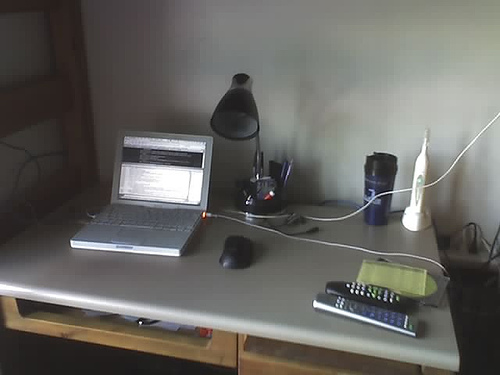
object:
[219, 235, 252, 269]
mouse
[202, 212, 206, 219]
indicator light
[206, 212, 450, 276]
wire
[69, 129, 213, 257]
computer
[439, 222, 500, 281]
wires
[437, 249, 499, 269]
strips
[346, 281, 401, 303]
buttons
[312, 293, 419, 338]
remote control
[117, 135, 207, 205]
screen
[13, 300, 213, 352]
cubbie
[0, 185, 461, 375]
desk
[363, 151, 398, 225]
cup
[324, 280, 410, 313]
remote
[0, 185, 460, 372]
table top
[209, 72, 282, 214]
lamp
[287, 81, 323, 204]
black shade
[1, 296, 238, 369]
drawer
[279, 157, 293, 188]
pencils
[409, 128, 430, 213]
electric brush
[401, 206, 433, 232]
base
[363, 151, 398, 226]
thermos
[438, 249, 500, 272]
power strip